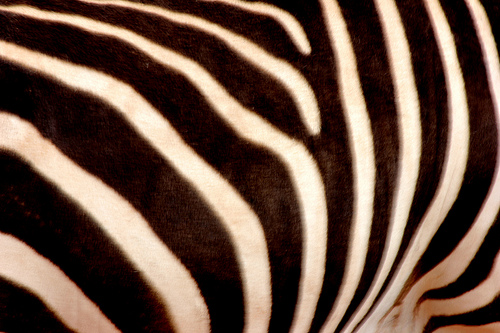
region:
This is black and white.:
[8, 10, 266, 115]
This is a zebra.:
[18, 5, 491, 286]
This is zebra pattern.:
[7, 100, 494, 314]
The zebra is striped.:
[26, 18, 472, 299]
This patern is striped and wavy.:
[193, 153, 499, 320]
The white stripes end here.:
[231, 5, 359, 160]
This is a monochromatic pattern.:
[25, 25, 445, 281]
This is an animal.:
[21, 33, 491, 313]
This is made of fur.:
[279, 47, 481, 233]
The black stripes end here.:
[384, 280, 439, 332]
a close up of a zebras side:
[1, 0, 499, 331]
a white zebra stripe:
[324, 1, 373, 289]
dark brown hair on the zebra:
[466, 93, 495, 177]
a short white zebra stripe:
[265, 0, 319, 55]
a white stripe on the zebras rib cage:
[147, 30, 298, 181]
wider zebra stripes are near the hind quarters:
[427, 1, 469, 223]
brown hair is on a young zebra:
[253, 165, 285, 211]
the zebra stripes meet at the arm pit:
[371, 294, 418, 331]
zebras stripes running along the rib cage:
[0, 77, 189, 227]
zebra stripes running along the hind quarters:
[380, 0, 499, 332]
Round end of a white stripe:
[289, 74, 323, 137]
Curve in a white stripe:
[218, 91, 278, 157]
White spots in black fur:
[4, 180, 50, 232]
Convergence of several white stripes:
[358, 278, 430, 331]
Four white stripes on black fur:
[317, 0, 499, 44]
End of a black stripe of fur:
[411, 288, 436, 310]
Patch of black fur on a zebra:
[144, 168, 176, 218]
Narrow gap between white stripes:
[298, 129, 328, 153]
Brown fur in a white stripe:
[156, 294, 174, 331]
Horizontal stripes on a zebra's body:
[438, 237, 498, 332]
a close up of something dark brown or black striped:
[20, 12, 490, 328]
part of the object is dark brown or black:
[60, 116, 160, 176]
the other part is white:
[155, 131, 285, 236]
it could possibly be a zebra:
[88, 107, 422, 317]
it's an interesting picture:
[21, 10, 499, 312]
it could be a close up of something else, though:
[28, 20, 498, 330]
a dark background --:
[66, 102, 406, 260]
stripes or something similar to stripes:
[88, 93, 491, 325]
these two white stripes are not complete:
[248, 3, 339, 139]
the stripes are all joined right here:
[366, 265, 466, 331]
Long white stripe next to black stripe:
[399, 0, 499, 331]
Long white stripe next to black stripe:
[340, 0, 427, 331]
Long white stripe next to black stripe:
[319, 0, 376, 331]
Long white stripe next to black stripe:
[0, 0, 327, 331]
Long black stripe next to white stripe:
[2, 8, 305, 332]